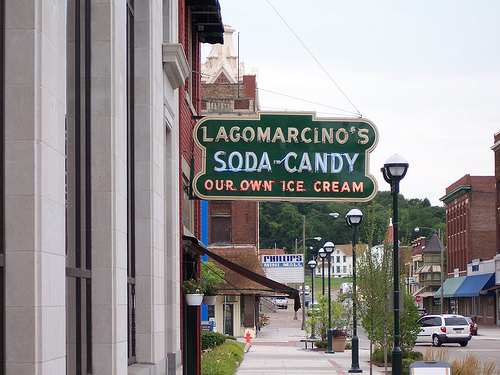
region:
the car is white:
[447, 313, 456, 337]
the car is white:
[433, 305, 446, 333]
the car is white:
[454, 315, 459, 330]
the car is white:
[450, 328, 459, 341]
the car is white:
[437, 318, 449, 337]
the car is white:
[439, 311, 452, 329]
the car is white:
[448, 320, 461, 338]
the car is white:
[444, 323, 456, 335]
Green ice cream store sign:
[202, 95, 375, 219]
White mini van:
[414, 303, 479, 343]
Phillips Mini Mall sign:
[254, 234, 309, 311]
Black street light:
[382, 147, 429, 351]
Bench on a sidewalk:
[265, 280, 326, 369]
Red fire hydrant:
[234, 327, 258, 353]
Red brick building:
[433, 155, 494, 342]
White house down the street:
[298, 221, 387, 371]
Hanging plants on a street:
[177, 257, 224, 324]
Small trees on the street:
[336, 236, 417, 373]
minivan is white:
[381, 296, 488, 361]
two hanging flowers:
[183, 253, 230, 323]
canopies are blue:
[433, 265, 499, 322]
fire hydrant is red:
[243, 325, 268, 354]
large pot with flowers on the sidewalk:
[325, 320, 361, 360]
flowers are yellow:
[200, 341, 242, 371]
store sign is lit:
[202, 96, 423, 251]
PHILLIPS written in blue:
[260, 241, 320, 276]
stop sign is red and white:
[410, 293, 446, 313]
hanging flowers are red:
[180, 274, 210, 303]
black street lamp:
[381, 155, 413, 362]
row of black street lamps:
[297, 154, 426, 360]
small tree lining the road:
[342, 241, 437, 366]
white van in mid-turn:
[406, 305, 480, 349]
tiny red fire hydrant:
[243, 325, 258, 343]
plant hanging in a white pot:
[178, 265, 210, 311]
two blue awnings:
[431, 272, 491, 299]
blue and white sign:
[257, 248, 313, 289]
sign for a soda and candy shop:
[176, 99, 398, 209]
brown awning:
[189, 234, 316, 314]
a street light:
[384, 151, 421, 373]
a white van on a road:
[398, 310, 473, 350]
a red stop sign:
[413, 293, 424, 304]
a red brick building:
[439, 175, 492, 274]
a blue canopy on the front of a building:
[458, 269, 494, 298]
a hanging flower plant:
[184, 261, 210, 312]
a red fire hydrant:
[241, 329, 254, 343]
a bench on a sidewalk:
[298, 335, 324, 349]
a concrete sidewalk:
[243, 306, 324, 373]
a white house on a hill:
[314, 239, 378, 281]